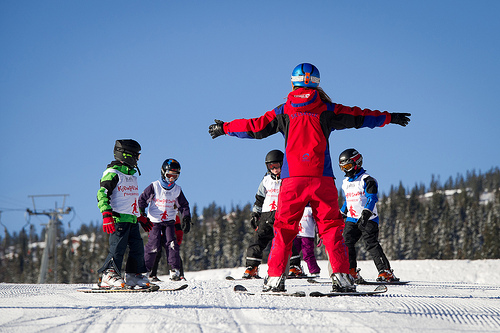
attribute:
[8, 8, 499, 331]
photo — more white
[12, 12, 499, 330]
background — black, white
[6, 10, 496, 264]
background — white